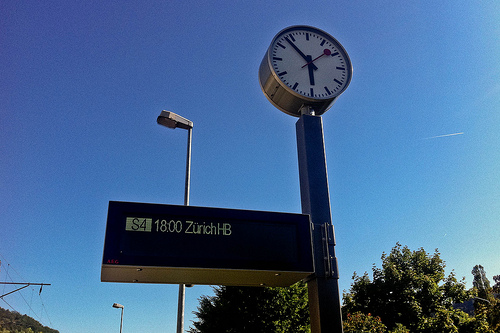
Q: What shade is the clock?
A: Silver, black and white.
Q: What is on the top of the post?
A: Clock.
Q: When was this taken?
A: 5:54.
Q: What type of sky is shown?
A: Clear blue.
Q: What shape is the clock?
A: Circle.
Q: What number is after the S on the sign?
A: 4.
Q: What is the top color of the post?
A: Blue.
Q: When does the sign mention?
A: 18:00.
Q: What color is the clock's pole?
A: Blue.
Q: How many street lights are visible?
A: 2.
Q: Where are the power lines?
A: Left.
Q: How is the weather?
A: Clear.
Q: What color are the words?
A: Yellow.